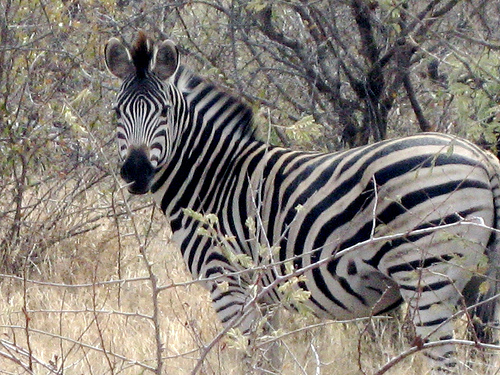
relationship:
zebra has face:
[102, 26, 497, 375] [109, 87, 175, 196]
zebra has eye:
[102, 26, 497, 375] [112, 103, 123, 118]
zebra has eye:
[102, 26, 497, 375] [159, 103, 170, 116]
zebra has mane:
[102, 26, 497, 375] [130, 30, 264, 141]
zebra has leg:
[102, 26, 497, 375] [386, 265, 459, 373]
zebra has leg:
[102, 26, 497, 375] [475, 260, 499, 345]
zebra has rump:
[102, 26, 497, 375] [442, 132, 499, 277]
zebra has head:
[102, 26, 497, 375] [100, 38, 181, 202]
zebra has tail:
[102, 26, 497, 375] [484, 165, 499, 250]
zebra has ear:
[102, 26, 497, 375] [101, 35, 136, 82]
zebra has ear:
[102, 26, 497, 375] [150, 39, 181, 87]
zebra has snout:
[102, 26, 497, 375] [118, 152, 156, 195]